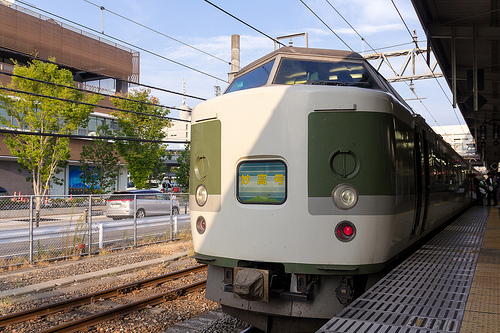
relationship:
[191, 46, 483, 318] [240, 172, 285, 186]
train has writing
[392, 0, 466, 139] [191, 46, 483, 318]
wire above train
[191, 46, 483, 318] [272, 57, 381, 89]
train has window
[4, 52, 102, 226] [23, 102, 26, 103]
tree has leaf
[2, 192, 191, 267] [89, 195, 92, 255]
fence has pole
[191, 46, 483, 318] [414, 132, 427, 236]
train has door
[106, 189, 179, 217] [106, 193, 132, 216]
minivan has rear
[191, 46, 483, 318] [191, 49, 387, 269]
train has front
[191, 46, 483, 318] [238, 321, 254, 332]
train on tracks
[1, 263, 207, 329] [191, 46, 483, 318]
track next to train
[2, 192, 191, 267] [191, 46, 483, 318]
fence next to train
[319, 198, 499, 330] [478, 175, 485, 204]
walkway for passenger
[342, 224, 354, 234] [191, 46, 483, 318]
light on train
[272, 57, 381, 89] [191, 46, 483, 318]
window on train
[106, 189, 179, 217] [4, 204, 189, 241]
minivan on street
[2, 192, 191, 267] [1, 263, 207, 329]
fence next to track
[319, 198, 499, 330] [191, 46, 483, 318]
walkway beside train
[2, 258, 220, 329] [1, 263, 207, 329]
gravel on track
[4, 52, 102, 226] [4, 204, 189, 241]
tree on street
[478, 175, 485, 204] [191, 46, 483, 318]
passenger entering train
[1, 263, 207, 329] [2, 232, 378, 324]
gravel on tracks